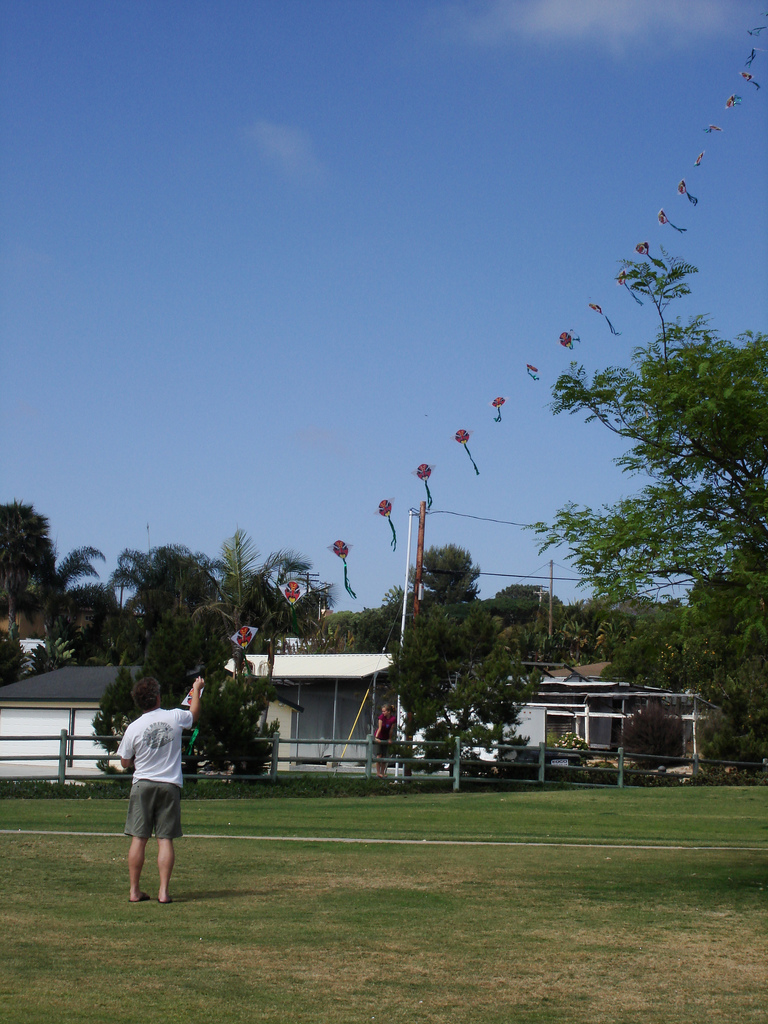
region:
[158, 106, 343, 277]
a view of sky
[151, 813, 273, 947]
leg of the person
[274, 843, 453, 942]
a view of grass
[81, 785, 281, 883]
shots of the person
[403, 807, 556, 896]
a line in grass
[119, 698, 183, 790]
man wearing a gray shirt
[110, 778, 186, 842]
man wearing gray pants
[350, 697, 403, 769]
girl leaning on a fence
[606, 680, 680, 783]
bush on the fence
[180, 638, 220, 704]
man holding a kite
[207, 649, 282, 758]
tree in front of the house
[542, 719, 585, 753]
white plant on the table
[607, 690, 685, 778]
tree in front of the house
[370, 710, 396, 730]
girl wearing a red shirt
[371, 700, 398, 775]
girl standing on a fence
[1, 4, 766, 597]
A blue sky above.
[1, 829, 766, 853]
A thin grey sidewalk through the grass.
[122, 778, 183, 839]
Grey shorts on a man.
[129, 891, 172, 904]
Black flip flops on a mans feet.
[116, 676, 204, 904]
A man in a white shirt flying a kite.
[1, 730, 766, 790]
Long wooden fence that gets smaller as it goes on.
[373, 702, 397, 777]
Girl in a red top.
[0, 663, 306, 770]
White doored garage wtih dark grey roof.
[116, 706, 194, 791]
White t-shirt on a man flying a kite.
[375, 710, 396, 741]
Red t-shirt on a girl.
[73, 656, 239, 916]
man with white shirt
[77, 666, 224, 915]
man with white shirt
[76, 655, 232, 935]
man with white shirt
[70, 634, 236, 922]
man with white shirt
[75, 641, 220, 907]
man with white shirt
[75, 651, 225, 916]
man with white shirt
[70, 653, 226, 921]
man with white shirt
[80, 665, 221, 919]
man with white shirt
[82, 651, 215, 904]
man with white shirt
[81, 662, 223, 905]
man flying kite